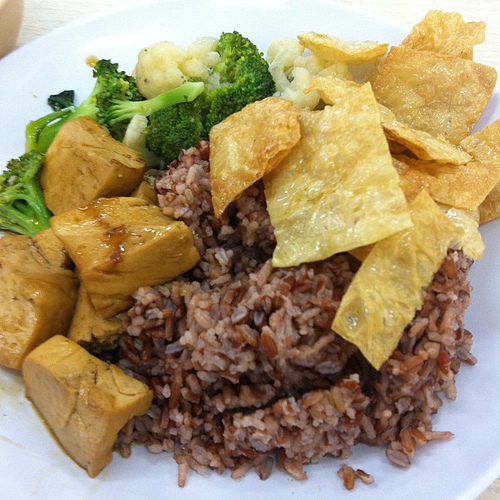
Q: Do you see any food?
A: Yes, there is food.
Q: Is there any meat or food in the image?
A: Yes, there is food.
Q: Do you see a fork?
A: No, there are no forks.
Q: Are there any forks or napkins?
A: No, there are no forks or napkins.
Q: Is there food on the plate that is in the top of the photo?
A: Yes, there is food on the plate.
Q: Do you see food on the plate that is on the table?
A: Yes, there is food on the plate.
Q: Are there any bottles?
A: No, there are no bottles.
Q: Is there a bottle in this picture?
A: No, there are no bottles.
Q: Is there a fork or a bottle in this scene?
A: No, there are no bottles or forks.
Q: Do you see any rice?
A: Yes, there is rice.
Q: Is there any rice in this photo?
A: Yes, there is rice.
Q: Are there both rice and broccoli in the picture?
A: Yes, there are both rice and broccoli.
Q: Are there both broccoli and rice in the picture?
A: Yes, there are both rice and broccoli.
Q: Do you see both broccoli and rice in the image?
A: Yes, there are both rice and broccoli.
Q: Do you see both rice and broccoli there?
A: Yes, there are both rice and broccoli.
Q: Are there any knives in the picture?
A: No, there are no knives.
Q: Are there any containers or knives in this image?
A: No, there are no knives or containers.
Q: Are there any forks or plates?
A: Yes, there is a plate.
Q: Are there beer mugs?
A: No, there are no beer mugs.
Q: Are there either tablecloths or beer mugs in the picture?
A: No, there are no beer mugs or tablecloths.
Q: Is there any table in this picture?
A: Yes, there is a table.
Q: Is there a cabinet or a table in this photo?
A: Yes, there is a table.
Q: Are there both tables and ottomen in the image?
A: No, there is a table but no ottomen.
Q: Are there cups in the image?
A: No, there are no cups.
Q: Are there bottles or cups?
A: No, there are no cups or bottles.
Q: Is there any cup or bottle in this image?
A: No, there are no cups or bottles.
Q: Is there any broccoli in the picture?
A: Yes, there is broccoli.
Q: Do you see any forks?
A: No, there are no forks.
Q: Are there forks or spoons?
A: No, there are no forks or spoons.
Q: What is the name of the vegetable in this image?
A: The vegetable is broccoli.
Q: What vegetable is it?
A: The vegetable is broccoli.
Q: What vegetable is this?
A: This is broccoli.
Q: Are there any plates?
A: Yes, there is a plate.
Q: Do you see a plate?
A: Yes, there is a plate.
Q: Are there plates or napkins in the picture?
A: Yes, there is a plate.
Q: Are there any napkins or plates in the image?
A: Yes, there is a plate.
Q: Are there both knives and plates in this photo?
A: No, there is a plate but no knives.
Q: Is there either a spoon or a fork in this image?
A: No, there are no forks or spoons.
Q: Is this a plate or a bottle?
A: This is a plate.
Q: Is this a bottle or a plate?
A: This is a plate.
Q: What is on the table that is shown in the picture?
A: The plate is on the table.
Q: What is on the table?
A: The plate is on the table.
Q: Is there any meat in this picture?
A: Yes, there is meat.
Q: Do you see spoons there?
A: No, there are no spoons.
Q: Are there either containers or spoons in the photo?
A: No, there are no spoons or containers.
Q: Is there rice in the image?
A: Yes, there is rice.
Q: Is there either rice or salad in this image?
A: Yes, there is rice.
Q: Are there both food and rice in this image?
A: Yes, there are both rice and food.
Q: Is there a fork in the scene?
A: No, there are no forks.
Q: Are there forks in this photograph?
A: No, there are no forks.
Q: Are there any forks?
A: No, there are no forks.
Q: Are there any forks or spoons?
A: No, there are no forks or spoons.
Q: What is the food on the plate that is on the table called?
A: The food is rice.